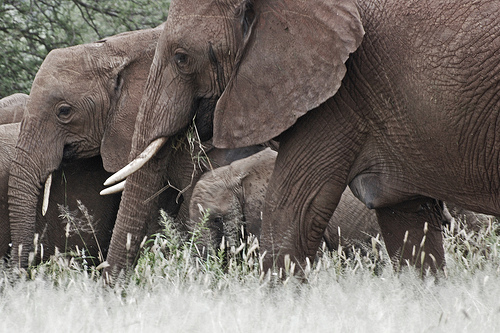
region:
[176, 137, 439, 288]
a small baby elephant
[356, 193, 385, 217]
a very large nipple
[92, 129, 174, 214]
a pair of tusks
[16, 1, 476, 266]
a pair of adult elephants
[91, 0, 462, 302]
an elephant eating hay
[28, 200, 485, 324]
a field of tall grasses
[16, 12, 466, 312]
elephants grazing in a field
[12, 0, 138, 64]
some tree foliage in the distance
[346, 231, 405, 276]
a few fern like plants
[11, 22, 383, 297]
a baby elephant with its mom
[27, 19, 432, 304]
herd of elephants in grass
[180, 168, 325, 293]
baby elephant walking between adults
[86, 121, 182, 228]
white tusks on elephant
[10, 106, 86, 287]
elephant trunk with tusk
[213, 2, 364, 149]
ear of large elephant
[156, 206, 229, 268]
wispy grass with elephants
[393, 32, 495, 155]
wrinkled gray elephant skin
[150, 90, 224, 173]
grass in elephant's mouth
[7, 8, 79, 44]
trees growing behind elephants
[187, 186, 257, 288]
baby elephant with trunk in the grass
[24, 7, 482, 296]
three elephants walking in a field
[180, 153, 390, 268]
baby elephant walking in a field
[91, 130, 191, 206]
tusks of an elephant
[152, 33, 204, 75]
eye of an elephant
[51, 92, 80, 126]
eye of an elephant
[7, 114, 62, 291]
trunk of an elephant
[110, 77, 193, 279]
trunk of an elephant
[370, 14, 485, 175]
wrinkled skin of an elephant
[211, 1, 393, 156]
ear of an elephant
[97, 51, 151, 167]
ear of an elephant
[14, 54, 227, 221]
the elephant has tusk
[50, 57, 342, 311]
the elephant has tusk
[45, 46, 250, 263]
the elephant has tusk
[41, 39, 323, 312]
the elephant has tusk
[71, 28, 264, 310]
the elephant has tusk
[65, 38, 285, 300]
the elephant has tusk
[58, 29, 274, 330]
the elephant has tusk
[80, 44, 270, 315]
the elephant has tusk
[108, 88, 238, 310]
the elephant has tusk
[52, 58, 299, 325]
the elephant has tusk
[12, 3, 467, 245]
elephants walking together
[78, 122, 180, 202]
white long thick tusks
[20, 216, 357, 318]
tall grass next to elephants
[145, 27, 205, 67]
elephants eyes are open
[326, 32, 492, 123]
the skin is wrinkled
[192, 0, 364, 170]
the ear is big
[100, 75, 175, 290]
the trunk is long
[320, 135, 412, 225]
the elephants chest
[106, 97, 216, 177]
elephant with grass in his mouth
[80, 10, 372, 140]
the elephant is brown